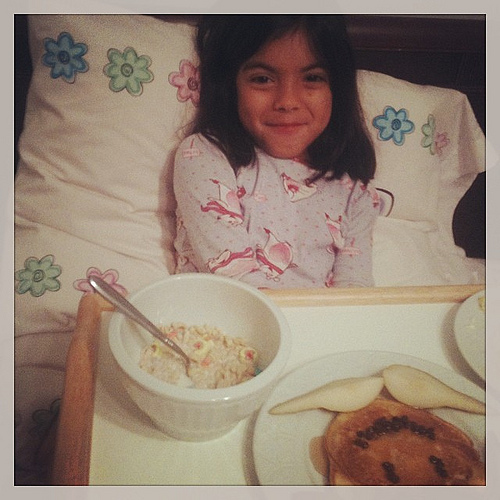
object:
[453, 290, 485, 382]
plate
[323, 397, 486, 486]
pancakes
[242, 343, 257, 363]
marshmallow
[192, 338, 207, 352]
marshmallow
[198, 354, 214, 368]
marshmallow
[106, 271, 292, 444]
bowl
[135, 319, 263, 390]
cereal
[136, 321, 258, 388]
milk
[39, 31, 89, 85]
flower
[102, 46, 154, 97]
flower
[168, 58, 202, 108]
flower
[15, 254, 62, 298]
flower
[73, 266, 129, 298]
flower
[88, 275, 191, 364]
handle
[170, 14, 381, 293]
girl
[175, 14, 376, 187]
hair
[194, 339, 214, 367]
fruit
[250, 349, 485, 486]
plate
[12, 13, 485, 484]
bed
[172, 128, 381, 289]
pajamas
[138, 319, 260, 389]
oatmeal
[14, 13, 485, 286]
pillow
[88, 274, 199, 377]
spoon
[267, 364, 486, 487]
slices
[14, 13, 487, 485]
pillowcase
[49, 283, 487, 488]
tray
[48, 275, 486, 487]
items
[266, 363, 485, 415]
pear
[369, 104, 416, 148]
flower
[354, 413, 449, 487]
happy face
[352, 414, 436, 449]
chocolate chips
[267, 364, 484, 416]
chips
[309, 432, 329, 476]
syrup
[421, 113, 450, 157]
flowers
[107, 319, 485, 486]
food